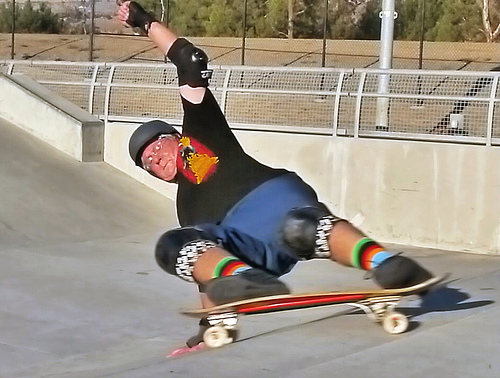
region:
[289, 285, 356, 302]
a skateboard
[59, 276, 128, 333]
a ramp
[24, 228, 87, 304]
the ramp is grey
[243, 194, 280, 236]
blue shorts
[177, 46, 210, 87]
an elbow pad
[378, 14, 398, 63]
a pole that is grey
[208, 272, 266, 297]
man is waring a shoe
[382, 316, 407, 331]
the wheels on the skateboard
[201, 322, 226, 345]
wheel is white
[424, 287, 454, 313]
a shadow on the ramp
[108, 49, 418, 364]
a man on a skateboard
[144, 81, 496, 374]
a man on aramp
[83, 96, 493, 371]
a man skateboarding ona ramp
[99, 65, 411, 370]
a man weraing a helmet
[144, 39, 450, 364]
a man at a skatepark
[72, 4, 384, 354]
a man wearing elbow gaurds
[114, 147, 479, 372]
a man wearing knee pads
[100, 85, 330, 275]
a man wearing a hsirt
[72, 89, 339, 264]
a man wearing black shirt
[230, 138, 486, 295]
a man wearin gsocks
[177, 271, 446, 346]
a skateboard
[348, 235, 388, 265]
a rainbow striped sock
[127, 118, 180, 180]
a man wearing a helmet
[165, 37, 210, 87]
a black elbow pad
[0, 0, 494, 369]
a man skateboarding on a skateboard ramp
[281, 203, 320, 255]
a black kneepad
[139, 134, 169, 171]
a pair of eyeglasses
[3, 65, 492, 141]
a row of wire fencing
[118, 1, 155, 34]
a black wrist guard